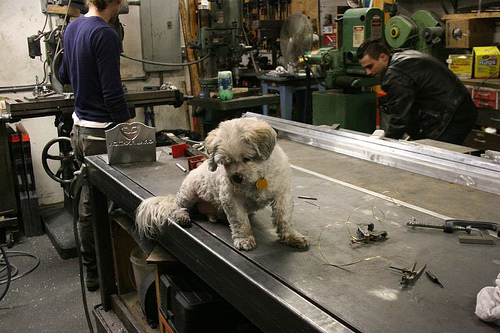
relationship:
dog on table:
[134, 117, 312, 250] [81, 126, 500, 332]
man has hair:
[354, 40, 480, 144] [356, 39, 391, 59]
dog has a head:
[134, 117, 312, 250] [205, 117, 277, 186]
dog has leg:
[134, 117, 312, 250] [270, 174, 311, 248]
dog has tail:
[134, 117, 312, 250] [132, 194, 180, 238]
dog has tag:
[134, 117, 312, 250] [256, 177, 269, 191]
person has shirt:
[59, 0, 131, 291] [58, 16, 132, 124]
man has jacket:
[354, 40, 480, 144] [380, 49, 470, 140]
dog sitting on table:
[134, 117, 312, 250] [81, 126, 500, 332]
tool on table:
[388, 259, 428, 286] [81, 126, 500, 332]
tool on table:
[165, 130, 210, 168] [81, 126, 500, 332]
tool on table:
[425, 269, 444, 287] [81, 126, 500, 332]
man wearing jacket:
[354, 40, 480, 144] [380, 49, 470, 140]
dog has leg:
[134, 117, 312, 250] [221, 175, 256, 250]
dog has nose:
[134, 117, 312, 250] [231, 172, 245, 183]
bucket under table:
[129, 247, 157, 313] [81, 126, 500, 332]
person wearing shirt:
[59, 0, 131, 291] [58, 16, 132, 124]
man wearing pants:
[354, 40, 480, 144] [439, 97, 478, 145]